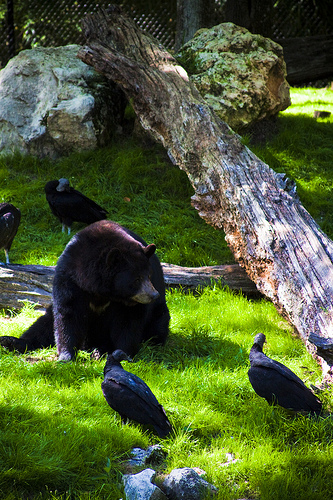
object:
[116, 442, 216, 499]
rocks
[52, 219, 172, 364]
bear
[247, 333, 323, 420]
bird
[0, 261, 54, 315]
structure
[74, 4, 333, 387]
log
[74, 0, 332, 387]
tree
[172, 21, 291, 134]
rock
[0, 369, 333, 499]
lawn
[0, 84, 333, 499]
grass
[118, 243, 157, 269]
hair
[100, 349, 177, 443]
bird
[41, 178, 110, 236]
bird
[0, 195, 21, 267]
bird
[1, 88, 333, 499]
ground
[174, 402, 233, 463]
sunlight